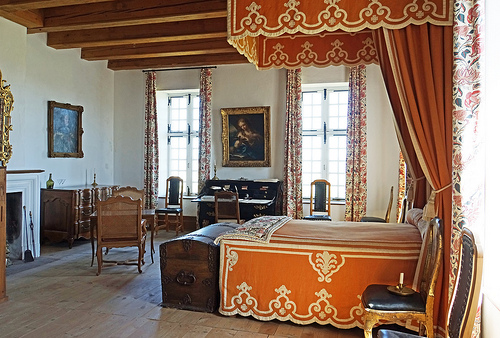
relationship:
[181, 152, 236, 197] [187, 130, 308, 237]
candlestick sitting on desk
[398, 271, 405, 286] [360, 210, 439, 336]
candle on chair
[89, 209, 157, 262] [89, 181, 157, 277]
small table has 2 chairs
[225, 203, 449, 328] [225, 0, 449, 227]
bed has orange canope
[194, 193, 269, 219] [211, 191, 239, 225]
wooden desk has chair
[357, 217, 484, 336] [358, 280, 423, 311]
chair has cushion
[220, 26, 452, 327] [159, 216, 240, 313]
bed has trunk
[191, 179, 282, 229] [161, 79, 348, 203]
desk between windows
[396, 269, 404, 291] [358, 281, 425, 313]
candle on seat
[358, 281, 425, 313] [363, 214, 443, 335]
seat on chair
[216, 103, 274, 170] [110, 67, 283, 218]
painting on wall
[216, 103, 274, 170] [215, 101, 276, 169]
painting on frame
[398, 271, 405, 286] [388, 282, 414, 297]
candle in holder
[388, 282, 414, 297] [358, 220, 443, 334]
holder on chair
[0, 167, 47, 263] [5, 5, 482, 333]
fireplace in bedroom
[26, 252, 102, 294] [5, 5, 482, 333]
floors in bedroom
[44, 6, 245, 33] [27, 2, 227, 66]
beam on ceiling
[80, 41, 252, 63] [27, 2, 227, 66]
beam on ceiling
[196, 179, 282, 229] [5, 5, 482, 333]
desk in bedroom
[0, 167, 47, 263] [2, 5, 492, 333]
fireplace in room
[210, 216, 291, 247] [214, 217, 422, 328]
blanket on beadspread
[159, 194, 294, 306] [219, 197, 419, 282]
trunk at foot of bed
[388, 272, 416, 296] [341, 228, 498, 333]
candlestick on chair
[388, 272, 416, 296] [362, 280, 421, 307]
candlestick on seat